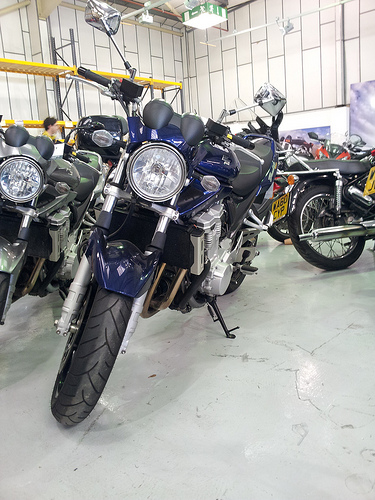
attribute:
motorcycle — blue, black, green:
[50, 67, 277, 427]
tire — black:
[50, 275, 131, 431]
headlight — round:
[129, 142, 184, 206]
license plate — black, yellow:
[270, 194, 288, 222]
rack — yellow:
[2, 55, 179, 94]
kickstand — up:
[205, 295, 235, 338]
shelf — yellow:
[1, 55, 182, 92]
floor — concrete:
[3, 226, 373, 497]